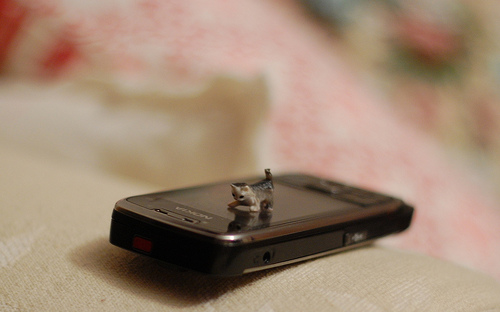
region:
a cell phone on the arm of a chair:
[15, 113, 431, 306]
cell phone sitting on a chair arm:
[16, 24, 484, 303]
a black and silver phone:
[98, 156, 425, 291]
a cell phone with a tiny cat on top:
[70, 142, 419, 289]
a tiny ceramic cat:
[217, 162, 282, 218]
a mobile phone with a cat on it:
[104, 152, 423, 287]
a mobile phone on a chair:
[100, 160, 421, 285]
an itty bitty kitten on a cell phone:
[213, 159, 283, 220]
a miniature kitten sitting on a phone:
[217, 161, 281, 217]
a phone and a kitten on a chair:
[33, 28, 494, 308]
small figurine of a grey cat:
[222, 171, 285, 226]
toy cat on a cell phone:
[90, 140, 431, 276]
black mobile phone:
[116, 165, 435, 280]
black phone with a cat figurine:
[87, 143, 449, 284]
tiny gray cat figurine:
[225, 167, 285, 224]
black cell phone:
[97, 126, 428, 282]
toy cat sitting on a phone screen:
[185, 173, 345, 236]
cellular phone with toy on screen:
[60, 140, 419, 307]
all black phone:
[113, 111, 419, 283]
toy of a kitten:
[219, 162, 318, 230]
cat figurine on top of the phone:
[216, 162, 286, 222]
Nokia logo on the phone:
[171, 201, 220, 228]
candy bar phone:
[85, 166, 451, 281]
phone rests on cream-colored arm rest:
[3, 143, 495, 303]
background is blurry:
[3, 4, 491, 269]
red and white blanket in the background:
[61, 7, 496, 250]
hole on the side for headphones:
[233, 230, 285, 284]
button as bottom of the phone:
[280, 160, 407, 210]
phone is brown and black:
[91, 155, 435, 289]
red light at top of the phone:
[109, 215, 175, 275]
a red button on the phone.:
[127, 219, 187, 266]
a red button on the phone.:
[110, 200, 174, 275]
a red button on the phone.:
[140, 213, 204, 287]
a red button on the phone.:
[69, 201, 191, 311]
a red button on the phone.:
[127, 242, 174, 307]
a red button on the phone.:
[132, 232, 178, 282]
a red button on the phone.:
[110, 223, 195, 305]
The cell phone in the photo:
[107, 166, 416, 281]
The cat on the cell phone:
[224, 162, 277, 220]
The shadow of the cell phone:
[63, 233, 259, 308]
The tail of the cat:
[260, 165, 275, 180]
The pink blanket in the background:
[1, 1, 498, 277]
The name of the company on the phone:
[173, 201, 214, 221]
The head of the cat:
[229, 179, 249, 203]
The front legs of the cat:
[225, 198, 258, 217]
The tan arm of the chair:
[0, 146, 499, 310]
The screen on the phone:
[165, 176, 353, 237]